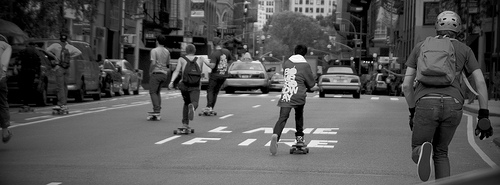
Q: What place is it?
A: It is a city.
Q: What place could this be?
A: It is a city.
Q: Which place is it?
A: It is a city.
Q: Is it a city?
A: Yes, it is a city.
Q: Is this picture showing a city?
A: Yes, it is showing a city.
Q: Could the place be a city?
A: Yes, it is a city.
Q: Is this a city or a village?
A: It is a city.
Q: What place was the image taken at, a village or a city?
A: It was taken at a city.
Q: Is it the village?
A: No, it is the city.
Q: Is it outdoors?
A: Yes, it is outdoors.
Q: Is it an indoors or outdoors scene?
A: It is outdoors.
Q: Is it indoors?
A: No, it is outdoors.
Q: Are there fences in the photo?
A: No, there are no fences.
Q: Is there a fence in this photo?
A: No, there are no fences.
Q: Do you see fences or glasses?
A: No, there are no fences or glasses.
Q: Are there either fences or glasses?
A: No, there are no fences or glasses.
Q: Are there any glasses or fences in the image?
A: No, there are no fences or glasses.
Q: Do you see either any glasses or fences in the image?
A: No, there are no fences or glasses.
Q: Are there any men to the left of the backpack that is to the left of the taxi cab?
A: Yes, there is a man to the left of the backpack.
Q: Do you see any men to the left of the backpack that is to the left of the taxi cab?
A: Yes, there is a man to the left of the backpack.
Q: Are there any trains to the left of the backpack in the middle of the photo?
A: No, there is a man to the left of the backpack.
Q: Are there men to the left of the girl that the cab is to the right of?
A: Yes, there is a man to the left of the girl.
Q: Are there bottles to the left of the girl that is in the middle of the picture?
A: No, there is a man to the left of the girl.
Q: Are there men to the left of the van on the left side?
A: Yes, there is a man to the left of the van.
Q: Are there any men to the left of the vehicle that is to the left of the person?
A: Yes, there is a man to the left of the van.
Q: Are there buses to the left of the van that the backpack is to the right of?
A: No, there is a man to the left of the van.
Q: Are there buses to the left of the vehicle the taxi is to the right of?
A: No, there is a man to the left of the van.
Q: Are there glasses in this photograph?
A: No, there are no glasses.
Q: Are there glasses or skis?
A: No, there are no glasses or skis.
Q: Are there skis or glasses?
A: No, there are no glasses or skis.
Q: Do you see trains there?
A: No, there are no trains.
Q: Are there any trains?
A: No, there are no trains.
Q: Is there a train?
A: No, there are no trains.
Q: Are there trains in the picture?
A: No, there are no trains.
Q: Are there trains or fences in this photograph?
A: No, there are no trains or fences.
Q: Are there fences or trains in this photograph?
A: No, there are no trains or fences.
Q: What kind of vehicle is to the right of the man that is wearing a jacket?
A: The vehicle is a car.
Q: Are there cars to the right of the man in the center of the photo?
A: Yes, there is a car to the right of the man.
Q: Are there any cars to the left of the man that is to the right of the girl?
A: No, the car is to the right of the man.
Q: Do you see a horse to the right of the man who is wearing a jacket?
A: No, there is a car to the right of the man.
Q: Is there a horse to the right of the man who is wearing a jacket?
A: No, there is a car to the right of the man.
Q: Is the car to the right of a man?
A: Yes, the car is to the right of a man.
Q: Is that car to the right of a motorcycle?
A: No, the car is to the right of a man.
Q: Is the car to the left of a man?
A: No, the car is to the right of a man.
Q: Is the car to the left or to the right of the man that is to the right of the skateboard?
A: The car is to the right of the man.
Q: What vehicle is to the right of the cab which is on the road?
A: The vehicle is a car.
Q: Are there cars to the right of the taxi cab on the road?
A: Yes, there is a car to the right of the cab.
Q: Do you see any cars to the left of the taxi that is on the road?
A: No, the car is to the right of the taxi.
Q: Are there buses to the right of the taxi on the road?
A: No, there is a car to the right of the taxi.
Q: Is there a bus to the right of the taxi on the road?
A: No, there is a car to the right of the taxi.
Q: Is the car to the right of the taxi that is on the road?
A: Yes, the car is to the right of the cab.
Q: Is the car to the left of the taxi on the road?
A: No, the car is to the right of the taxi.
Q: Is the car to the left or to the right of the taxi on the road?
A: The car is to the right of the taxi.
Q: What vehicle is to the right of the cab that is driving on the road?
A: The vehicle is a car.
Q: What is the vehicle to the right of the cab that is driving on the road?
A: The vehicle is a car.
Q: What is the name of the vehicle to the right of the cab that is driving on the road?
A: The vehicle is a car.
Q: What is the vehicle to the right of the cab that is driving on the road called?
A: The vehicle is a car.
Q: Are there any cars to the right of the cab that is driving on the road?
A: Yes, there is a car to the right of the taxi.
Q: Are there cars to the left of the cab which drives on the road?
A: No, the car is to the right of the taxi.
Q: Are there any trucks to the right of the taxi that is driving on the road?
A: No, there is a car to the right of the taxi.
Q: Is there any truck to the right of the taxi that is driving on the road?
A: No, there is a car to the right of the taxi.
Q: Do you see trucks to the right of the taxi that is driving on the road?
A: No, there is a car to the right of the taxi.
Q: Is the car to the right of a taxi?
A: Yes, the car is to the right of a taxi.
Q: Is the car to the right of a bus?
A: No, the car is to the right of a taxi.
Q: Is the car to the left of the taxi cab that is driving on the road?
A: No, the car is to the right of the taxi.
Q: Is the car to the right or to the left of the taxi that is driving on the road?
A: The car is to the right of the taxi.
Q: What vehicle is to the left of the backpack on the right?
A: The vehicle is a car.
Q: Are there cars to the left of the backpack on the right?
A: Yes, there is a car to the left of the backpack.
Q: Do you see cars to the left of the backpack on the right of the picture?
A: Yes, there is a car to the left of the backpack.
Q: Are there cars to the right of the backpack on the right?
A: No, the car is to the left of the backpack.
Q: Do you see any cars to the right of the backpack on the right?
A: No, the car is to the left of the backpack.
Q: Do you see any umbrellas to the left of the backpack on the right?
A: No, there is a car to the left of the backpack.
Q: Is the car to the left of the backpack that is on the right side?
A: Yes, the car is to the left of the backpack.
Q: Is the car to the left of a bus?
A: No, the car is to the left of the backpack.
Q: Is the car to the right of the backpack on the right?
A: No, the car is to the left of the backpack.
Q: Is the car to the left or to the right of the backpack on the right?
A: The car is to the left of the backpack.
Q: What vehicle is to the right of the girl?
A: The vehicle is a car.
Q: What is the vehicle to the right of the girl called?
A: The vehicle is a car.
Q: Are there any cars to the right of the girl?
A: Yes, there is a car to the right of the girl.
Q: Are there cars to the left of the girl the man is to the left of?
A: No, the car is to the right of the girl.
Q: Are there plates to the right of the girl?
A: No, there is a car to the right of the girl.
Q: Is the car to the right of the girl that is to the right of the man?
A: Yes, the car is to the right of the girl.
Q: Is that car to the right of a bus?
A: No, the car is to the right of the girl.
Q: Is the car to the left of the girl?
A: No, the car is to the right of the girl.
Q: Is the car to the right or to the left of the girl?
A: The car is to the right of the girl.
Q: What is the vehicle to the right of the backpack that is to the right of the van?
A: The vehicle is a car.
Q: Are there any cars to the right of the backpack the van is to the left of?
A: Yes, there is a car to the right of the backpack.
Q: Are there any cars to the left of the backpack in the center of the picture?
A: No, the car is to the right of the backpack.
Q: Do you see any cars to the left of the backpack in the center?
A: No, the car is to the right of the backpack.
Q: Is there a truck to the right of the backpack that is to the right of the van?
A: No, there is a car to the right of the backpack.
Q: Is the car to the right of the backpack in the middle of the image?
A: Yes, the car is to the right of the backpack.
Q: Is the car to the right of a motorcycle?
A: No, the car is to the right of the backpack.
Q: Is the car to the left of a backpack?
A: No, the car is to the right of a backpack.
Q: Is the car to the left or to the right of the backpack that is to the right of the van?
A: The car is to the right of the backpack.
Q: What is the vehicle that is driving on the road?
A: The vehicle is a car.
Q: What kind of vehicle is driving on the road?
A: The vehicle is a car.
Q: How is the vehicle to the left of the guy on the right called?
A: The vehicle is a car.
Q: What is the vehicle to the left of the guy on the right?
A: The vehicle is a car.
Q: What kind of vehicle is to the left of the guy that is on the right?
A: The vehicle is a car.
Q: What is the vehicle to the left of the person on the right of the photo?
A: The vehicle is a car.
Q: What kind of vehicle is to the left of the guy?
A: The vehicle is a car.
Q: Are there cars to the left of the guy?
A: Yes, there is a car to the left of the guy.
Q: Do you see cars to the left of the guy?
A: Yes, there is a car to the left of the guy.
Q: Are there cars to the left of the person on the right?
A: Yes, there is a car to the left of the guy.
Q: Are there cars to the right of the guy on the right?
A: No, the car is to the left of the guy.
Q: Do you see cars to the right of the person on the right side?
A: No, the car is to the left of the guy.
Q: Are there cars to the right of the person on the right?
A: No, the car is to the left of the guy.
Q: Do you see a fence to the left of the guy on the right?
A: No, there is a car to the left of the guy.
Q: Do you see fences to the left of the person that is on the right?
A: No, there is a car to the left of the guy.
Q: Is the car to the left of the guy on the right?
A: Yes, the car is to the left of the guy.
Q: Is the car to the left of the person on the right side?
A: Yes, the car is to the left of the guy.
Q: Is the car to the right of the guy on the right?
A: No, the car is to the left of the guy.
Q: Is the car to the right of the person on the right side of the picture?
A: No, the car is to the left of the guy.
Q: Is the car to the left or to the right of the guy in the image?
A: The car is to the left of the guy.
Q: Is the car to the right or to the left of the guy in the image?
A: The car is to the left of the guy.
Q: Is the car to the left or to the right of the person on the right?
A: The car is to the left of the guy.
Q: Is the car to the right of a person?
A: Yes, the car is to the right of a person.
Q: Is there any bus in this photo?
A: No, there are no buses.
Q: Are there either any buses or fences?
A: No, there are no buses or fences.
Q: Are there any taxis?
A: Yes, there is a taxi.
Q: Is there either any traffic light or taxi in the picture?
A: Yes, there is a taxi.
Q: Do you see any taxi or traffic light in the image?
A: Yes, there is a taxi.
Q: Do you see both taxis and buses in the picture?
A: No, there is a taxi but no buses.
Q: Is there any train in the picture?
A: No, there are no trains.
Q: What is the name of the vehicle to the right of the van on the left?
A: The vehicle is a taxi.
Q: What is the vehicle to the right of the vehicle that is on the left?
A: The vehicle is a taxi.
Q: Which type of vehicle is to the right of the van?
A: The vehicle is a taxi.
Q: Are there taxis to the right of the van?
A: Yes, there is a taxi to the right of the van.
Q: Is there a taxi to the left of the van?
A: No, the taxi is to the right of the van.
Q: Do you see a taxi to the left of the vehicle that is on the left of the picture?
A: No, the taxi is to the right of the van.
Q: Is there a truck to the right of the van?
A: No, there is a taxi to the right of the van.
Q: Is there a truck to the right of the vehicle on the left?
A: No, there is a taxi to the right of the van.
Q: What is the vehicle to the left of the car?
A: The vehicle is a taxi.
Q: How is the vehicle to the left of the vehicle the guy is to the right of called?
A: The vehicle is a taxi.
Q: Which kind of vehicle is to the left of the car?
A: The vehicle is a taxi.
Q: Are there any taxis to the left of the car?
A: Yes, there is a taxi to the left of the car.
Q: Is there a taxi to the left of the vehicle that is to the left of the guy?
A: Yes, there is a taxi to the left of the car.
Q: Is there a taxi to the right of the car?
A: No, the taxi is to the left of the car.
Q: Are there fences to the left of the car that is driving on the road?
A: No, there is a taxi to the left of the car.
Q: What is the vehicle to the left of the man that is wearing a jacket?
A: The vehicle is a taxi.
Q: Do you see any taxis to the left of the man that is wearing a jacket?
A: Yes, there is a taxi to the left of the man.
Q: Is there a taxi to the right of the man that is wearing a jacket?
A: No, the taxi is to the left of the man.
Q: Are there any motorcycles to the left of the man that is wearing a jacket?
A: No, there is a taxi to the left of the man.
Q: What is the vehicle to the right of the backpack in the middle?
A: The vehicle is a taxi.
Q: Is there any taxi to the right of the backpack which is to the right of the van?
A: Yes, there is a taxi to the right of the backpack.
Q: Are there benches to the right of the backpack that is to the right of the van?
A: No, there is a taxi to the right of the backpack.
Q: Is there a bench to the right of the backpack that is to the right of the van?
A: No, there is a taxi to the right of the backpack.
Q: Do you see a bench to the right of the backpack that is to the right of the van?
A: No, there is a taxi to the right of the backpack.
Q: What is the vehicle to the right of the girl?
A: The vehicle is a taxi.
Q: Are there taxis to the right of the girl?
A: Yes, there is a taxi to the right of the girl.